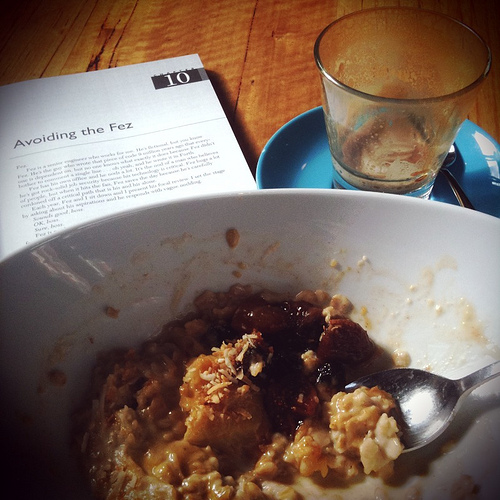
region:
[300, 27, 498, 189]
a glass on a table.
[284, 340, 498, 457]
a spoon in a bowl.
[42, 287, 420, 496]
porage in a white bowl.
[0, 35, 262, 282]
a white paper on a table.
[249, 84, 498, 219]
a blue plate on a table.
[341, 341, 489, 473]
a metal spoon in a bowl.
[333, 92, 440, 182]
water in a glass.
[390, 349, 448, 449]
light reflecting on a spoon.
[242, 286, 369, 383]
black food in a bowl.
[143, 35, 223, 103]
the number 10 on a paper.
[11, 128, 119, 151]
The magazine says "Reading the Fez"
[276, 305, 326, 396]
There is a portion of maple syrup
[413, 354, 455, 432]
There is a silver spoon in the bowl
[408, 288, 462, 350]
There is a white bowl on the table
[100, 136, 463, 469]
Jackson Mingus took this photograph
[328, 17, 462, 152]
There is an empty glass in the photo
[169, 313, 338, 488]
This is a portion of oatmeal in a bowl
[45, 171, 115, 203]
There are many words on this page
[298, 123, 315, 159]
There is a blue plate that is visible here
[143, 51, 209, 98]
There is the number 10 on the magazine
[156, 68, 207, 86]
chapter number on the page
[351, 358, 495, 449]
metal spoon in the bowl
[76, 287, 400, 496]
food in a white bowl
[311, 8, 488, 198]
small empty glass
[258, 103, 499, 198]
small blue plate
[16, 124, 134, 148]
title on the top of the page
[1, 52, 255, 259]
open book on the table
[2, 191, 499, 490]
round white bowl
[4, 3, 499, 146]
light wooden table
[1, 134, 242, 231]
black text in the book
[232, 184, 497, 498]
spoon in a bowel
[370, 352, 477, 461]
reflection of light in a spoon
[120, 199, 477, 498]
food in a bowel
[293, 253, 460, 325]
crumbs on the side of a bowel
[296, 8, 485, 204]
glass next to the bowel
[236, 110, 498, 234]
saucer next to the bowel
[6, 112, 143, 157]
words on the paper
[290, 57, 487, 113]
lip of the cup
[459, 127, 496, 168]
reflection on the saucer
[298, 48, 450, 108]
grit on the glass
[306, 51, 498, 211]
an empty glass on saucer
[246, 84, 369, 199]
the saucer is blue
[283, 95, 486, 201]
the saucer is blue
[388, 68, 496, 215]
the saucer is blue